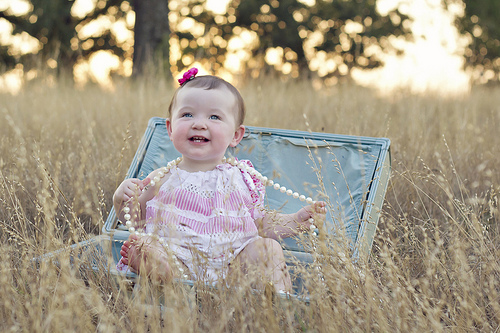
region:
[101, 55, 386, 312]
baby sitting a dry field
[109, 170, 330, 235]
string of pears held in both of baby's hands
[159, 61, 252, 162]
pink flower hair clip in thin dark hair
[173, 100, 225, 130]
baby's bright clear blue eyes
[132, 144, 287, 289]
baby wearing pink and white dress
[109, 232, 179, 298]
baby foot showing through wheat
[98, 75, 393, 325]
baby sitting in light blue suitcase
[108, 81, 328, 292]
string of pearls draped over baby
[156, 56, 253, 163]
smiling face of child with blue eyes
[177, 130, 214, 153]
baby teeth in open mouthed smile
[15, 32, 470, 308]
A baby is having a good time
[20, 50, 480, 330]
A baby is looking very cute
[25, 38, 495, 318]
The baby is showing a nice smile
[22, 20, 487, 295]
The baby is playing with some beads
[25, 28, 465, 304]
The baby has something in her hair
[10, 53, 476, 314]
The baby is in a field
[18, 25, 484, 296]
A baby is in tall grass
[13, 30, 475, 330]
A baby is smiling at mom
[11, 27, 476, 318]
A baby is showing her teeth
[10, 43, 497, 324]
A baby has pretty blue eyes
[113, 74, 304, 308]
Smiling baby in pink clothing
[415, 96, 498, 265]
Baby sitting in a wheat field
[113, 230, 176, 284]
Baby has beauiful toes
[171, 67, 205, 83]
Baby has a deep pink bow in hair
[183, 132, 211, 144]
Baby has first teeth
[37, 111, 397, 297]
Baby is sitting in suitcase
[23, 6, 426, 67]
Trees off in the distance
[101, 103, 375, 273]
The old suitcase is blue in color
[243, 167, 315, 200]
Baby is holding pearl necklace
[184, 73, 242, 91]
Baby has deep brown hair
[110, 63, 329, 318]
baby sitting in field of tall yellow straw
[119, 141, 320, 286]
long pearl necklace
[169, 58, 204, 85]
pink bow on baby's head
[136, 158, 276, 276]
pink and white baby dress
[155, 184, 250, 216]
pink and white striped pattern on pink and white dress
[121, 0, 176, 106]
brown tree trunk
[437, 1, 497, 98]
green tree and foliage behind straw field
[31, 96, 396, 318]
open blue suitcase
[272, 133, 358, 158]
torn interior edge of suitcase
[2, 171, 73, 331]
buds on top of straw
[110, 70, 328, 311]
baby sitting in grass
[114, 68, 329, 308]
baby wearing white pearls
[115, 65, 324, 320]
baby wearing pink bow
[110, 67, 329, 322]
baby wearing pink dress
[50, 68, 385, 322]
baby sitting in suitcase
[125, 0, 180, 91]
tree has brown bark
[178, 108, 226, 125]
baby has blue eyes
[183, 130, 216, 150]
baby has white teeth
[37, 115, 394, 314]
suitcase is light blue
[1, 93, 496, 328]
wheat field is high